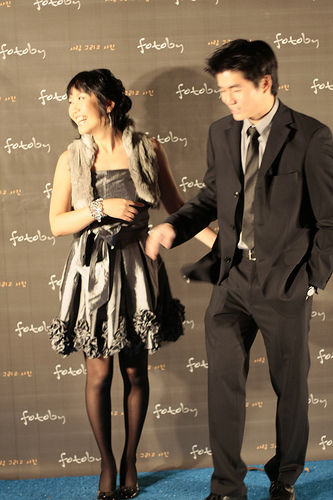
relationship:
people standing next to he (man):
[22, 69, 188, 497] [145, 38, 333, 500]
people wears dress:
[48, 69, 216, 498] [67, 177, 183, 356]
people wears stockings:
[48, 69, 216, 498] [84, 351, 149, 496]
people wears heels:
[48, 69, 216, 498] [92, 460, 141, 497]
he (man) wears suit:
[145, 38, 333, 500] [154, 97, 331, 492]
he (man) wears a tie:
[145, 38, 333, 500] [240, 119, 259, 251]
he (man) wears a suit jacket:
[145, 38, 333, 500] [144, 96, 331, 309]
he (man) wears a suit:
[146, 38, 331, 500] [175, 106, 331, 483]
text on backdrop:
[17, 409, 66, 424] [104, 1, 153, 61]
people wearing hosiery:
[48, 69, 216, 498] [85, 354, 150, 496]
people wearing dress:
[48, 69, 216, 498] [42, 234, 185, 361]